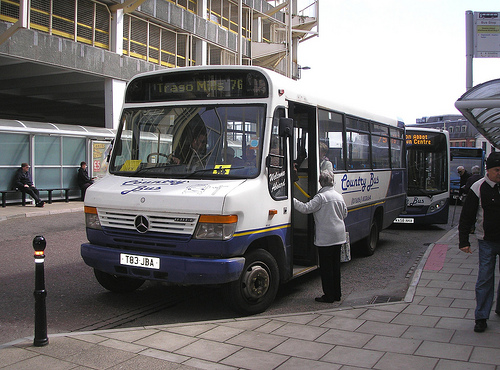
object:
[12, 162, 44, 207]
man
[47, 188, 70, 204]
bench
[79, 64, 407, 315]
bus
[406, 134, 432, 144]
sign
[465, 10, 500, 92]
stop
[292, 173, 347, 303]
woman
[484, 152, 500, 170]
cap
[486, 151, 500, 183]
head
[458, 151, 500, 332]
man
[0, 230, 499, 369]
sidewalk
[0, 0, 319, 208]
building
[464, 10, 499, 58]
sign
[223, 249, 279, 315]
tire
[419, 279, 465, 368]
sidewalk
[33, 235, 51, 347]
pole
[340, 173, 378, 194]
letters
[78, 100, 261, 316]
face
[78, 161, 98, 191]
woman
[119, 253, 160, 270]
license plate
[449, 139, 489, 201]
bus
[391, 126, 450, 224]
bus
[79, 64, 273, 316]
front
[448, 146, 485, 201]
front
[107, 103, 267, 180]
front window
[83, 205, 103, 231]
light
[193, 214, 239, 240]
light